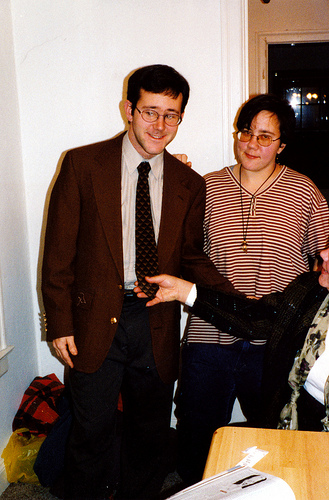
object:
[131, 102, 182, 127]
glasses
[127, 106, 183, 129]
pair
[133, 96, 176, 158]
face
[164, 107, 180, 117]
eyebrow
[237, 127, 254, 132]
eyebrow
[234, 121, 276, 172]
face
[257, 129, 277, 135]
eyebrow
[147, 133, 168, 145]
mouth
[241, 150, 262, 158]
mouth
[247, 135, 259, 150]
nose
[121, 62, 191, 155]
head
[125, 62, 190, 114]
hair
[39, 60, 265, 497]
man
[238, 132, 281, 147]
glasses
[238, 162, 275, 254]
chain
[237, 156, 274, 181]
neck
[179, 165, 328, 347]
shirt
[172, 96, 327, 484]
person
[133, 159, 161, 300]
tie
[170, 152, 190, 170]
hand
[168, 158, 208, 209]
shoulder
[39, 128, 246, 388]
jacket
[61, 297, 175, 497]
pants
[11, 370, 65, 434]
object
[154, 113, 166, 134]
nose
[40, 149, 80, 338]
arm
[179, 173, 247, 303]
arm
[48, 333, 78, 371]
hand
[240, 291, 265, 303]
hand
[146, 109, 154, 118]
eye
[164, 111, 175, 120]
eye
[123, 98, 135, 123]
ear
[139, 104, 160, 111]
eyebrow